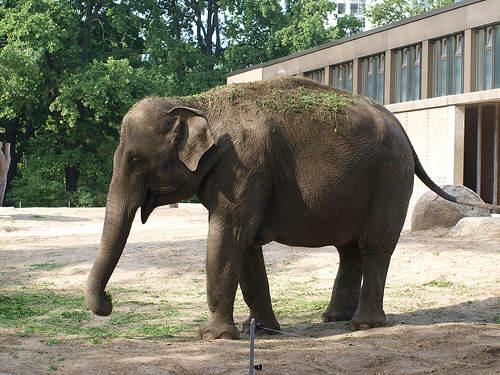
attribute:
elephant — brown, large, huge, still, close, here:
[108, 81, 467, 305]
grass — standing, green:
[278, 81, 347, 129]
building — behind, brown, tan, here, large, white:
[355, 20, 490, 110]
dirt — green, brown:
[129, 270, 199, 366]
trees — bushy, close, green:
[31, 11, 178, 99]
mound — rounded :
[0, 324, 498, 367]